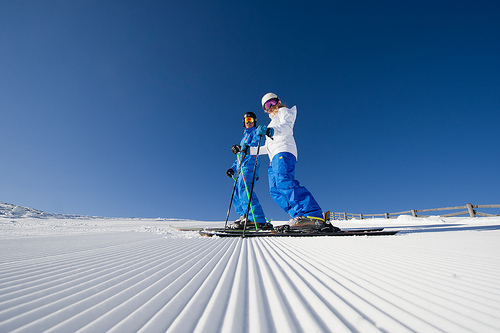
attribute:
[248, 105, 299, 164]
jacket — white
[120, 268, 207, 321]
snow — perfectly groomed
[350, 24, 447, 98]
sky — clear, blue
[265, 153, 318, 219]
pants — snow, pair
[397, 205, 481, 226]
fence — wooden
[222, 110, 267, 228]
man — blue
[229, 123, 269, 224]
suit — snow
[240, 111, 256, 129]
helmet — black, ski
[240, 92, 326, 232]
person — one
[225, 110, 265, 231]
person — one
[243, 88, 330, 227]
person — one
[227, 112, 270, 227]
person — one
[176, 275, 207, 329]
line — many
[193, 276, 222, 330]
line — many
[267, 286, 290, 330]
line — many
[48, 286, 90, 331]
line — many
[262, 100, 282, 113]
goggles — ski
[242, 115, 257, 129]
goggles — ski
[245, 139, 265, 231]
pole — ski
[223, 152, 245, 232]
pole — ski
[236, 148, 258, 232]
pole — ski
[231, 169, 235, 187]
pole — ski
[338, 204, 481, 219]
fence — wooden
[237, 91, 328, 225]
woman — stationary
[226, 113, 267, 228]
woman — stationary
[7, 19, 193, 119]
ski — dark blue